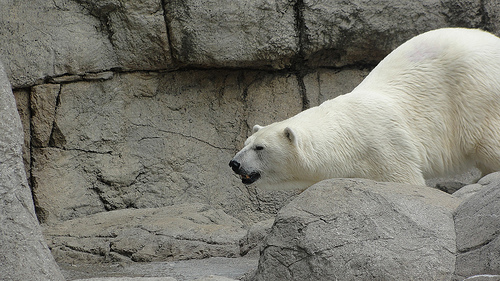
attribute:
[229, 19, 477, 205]
bear — polar, white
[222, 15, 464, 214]
bear — polar, head, white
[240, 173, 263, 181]
mouth — open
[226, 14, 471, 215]
body — full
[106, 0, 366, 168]
rock — overhanging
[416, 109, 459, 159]
fur — soft, white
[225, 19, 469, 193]
bear — polar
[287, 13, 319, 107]
line — black, crack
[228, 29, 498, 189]
polar bear — furry, white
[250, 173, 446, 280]
rock — round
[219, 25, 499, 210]
polar bear — furry